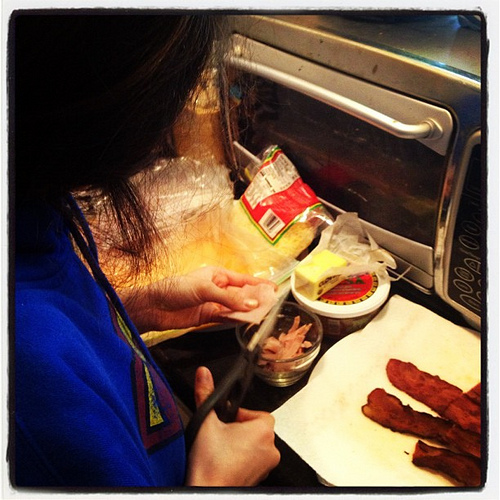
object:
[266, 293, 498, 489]
cutting board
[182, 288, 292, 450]
scissors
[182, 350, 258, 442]
handle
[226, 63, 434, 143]
bar handle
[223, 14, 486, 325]
oven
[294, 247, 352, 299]
butter stick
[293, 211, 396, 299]
wrapper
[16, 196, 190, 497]
shirt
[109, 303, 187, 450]
emblem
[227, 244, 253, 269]
shredded cheese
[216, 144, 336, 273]
bag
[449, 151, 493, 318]
touch controls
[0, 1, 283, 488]
person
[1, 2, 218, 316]
hair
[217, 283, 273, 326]
meat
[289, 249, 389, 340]
sa container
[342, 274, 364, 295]
sa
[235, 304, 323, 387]
glass container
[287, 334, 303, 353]
meat strips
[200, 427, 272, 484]
skin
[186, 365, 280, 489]
hand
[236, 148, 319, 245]
food label